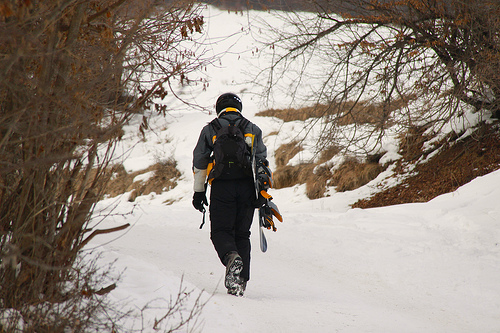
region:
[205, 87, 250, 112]
THE MAN IS WEARING A BLACK HELMET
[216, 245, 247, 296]
THE MAN IS WEARING BOOTS WITH SNOW ON THEM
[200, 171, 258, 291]
THE MAN IS WEARING BLACK PANTS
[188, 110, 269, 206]
THE MAN IS WEARING A GREY JACKET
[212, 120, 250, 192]
THE MAN IS WEARING A BACKPACK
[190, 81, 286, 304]
THE MAN IS WALKING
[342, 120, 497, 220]
THE GROUND IS SHOWING THROUGH THE SNOW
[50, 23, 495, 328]
THE SNOW IS SURROUNDING THE MAN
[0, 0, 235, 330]
THE BUSH IS BROWN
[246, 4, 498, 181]
THE BUSH IS DRY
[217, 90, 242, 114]
a man is wearing a black helmet on his head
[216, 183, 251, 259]
black pants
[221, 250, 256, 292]
the man is wearing black shoes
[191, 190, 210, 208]
the person is wearing black gloves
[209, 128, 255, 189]
it is a black backpack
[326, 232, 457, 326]
snow covers the ground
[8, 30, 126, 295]
some trees with no leaves on the them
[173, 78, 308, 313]
a person walks in the snow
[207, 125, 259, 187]
a person carrying a backpack on their back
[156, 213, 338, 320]
snow covers the ground and surrounding areas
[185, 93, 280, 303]
a person walking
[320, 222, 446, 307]
the snow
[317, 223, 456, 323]
the snow is white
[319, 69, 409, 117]
tree branches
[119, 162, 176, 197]
dirt in the snow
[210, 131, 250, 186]
a black backpack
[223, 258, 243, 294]
person is wearing shoes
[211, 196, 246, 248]
black pants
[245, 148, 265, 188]
person is holding skis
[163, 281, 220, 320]
small tree branch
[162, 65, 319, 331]
man walking on the snow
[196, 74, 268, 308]
man walking on the snow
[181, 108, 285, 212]
the jacket is gray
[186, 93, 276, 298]
a single man walking on the snow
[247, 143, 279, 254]
the snowboard being carried in the man's hand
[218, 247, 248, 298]
the shoes on the man's feet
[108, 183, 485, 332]
the snow on the ground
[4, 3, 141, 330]
some bare brown trees off to the side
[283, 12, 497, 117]
a tree with some brown leaves on it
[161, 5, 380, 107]
some more snow on the ground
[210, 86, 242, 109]
the helmet on the man's head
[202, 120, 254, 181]
the backpack the man is wearing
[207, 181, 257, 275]
the black pants the man is wearing